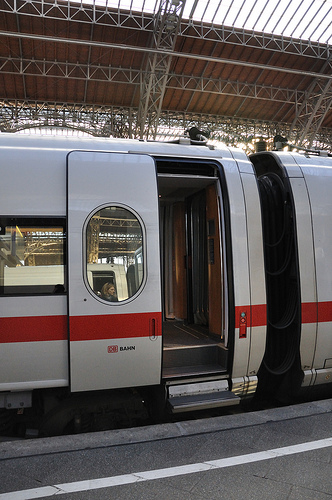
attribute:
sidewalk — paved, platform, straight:
[2, 397, 330, 498]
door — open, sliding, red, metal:
[154, 158, 232, 379]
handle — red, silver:
[136, 311, 161, 346]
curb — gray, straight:
[1, 396, 331, 458]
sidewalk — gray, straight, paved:
[0, 411, 331, 499]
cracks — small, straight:
[198, 461, 310, 495]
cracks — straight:
[24, 470, 60, 492]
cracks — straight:
[125, 466, 151, 490]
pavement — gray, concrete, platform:
[0, 391, 328, 495]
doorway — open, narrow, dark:
[149, 151, 235, 386]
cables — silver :
[135, 0, 188, 139]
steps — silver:
[160, 379, 244, 414]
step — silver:
[155, 371, 291, 444]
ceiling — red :
[11, 21, 329, 121]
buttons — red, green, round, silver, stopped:
[233, 300, 258, 344]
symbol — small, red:
[103, 341, 121, 355]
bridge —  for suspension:
[220, 29, 294, 71]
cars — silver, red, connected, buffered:
[3, 130, 330, 414]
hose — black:
[257, 167, 305, 388]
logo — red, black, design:
[103, 337, 145, 360]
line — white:
[0, 437, 328, 499]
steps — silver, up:
[161, 348, 236, 411]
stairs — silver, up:
[159, 344, 240, 409]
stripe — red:
[1, 295, 330, 345]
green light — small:
[238, 310, 248, 319]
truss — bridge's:
[9, 4, 52, 15]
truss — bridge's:
[222, 26, 232, 36]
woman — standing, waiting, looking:
[87, 265, 129, 317]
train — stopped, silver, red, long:
[9, 100, 329, 386]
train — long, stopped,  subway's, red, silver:
[4, 97, 330, 412]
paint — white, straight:
[160, 420, 301, 484]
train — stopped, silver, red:
[43, 123, 264, 311]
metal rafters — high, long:
[2, 108, 241, 142]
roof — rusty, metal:
[0, 1, 331, 133]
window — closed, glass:
[78, 201, 148, 307]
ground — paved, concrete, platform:
[9, 396, 313, 489]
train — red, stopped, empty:
[0, 135, 268, 409]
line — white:
[3, 435, 320, 488]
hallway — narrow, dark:
[157, 176, 227, 367]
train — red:
[221, 155, 265, 385]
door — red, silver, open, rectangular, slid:
[69, 153, 163, 392]